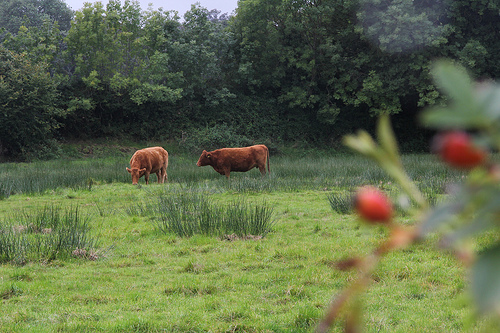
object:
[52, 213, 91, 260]
grass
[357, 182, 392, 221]
flower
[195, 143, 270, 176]
cow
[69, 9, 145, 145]
trees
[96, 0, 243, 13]
sky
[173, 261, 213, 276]
dirt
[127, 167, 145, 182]
head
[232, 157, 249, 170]
stomach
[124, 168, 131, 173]
ear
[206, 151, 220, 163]
neck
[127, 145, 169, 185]
cow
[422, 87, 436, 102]
leaf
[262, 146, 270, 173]
tail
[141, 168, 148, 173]
ear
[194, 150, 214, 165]
head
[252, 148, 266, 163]
hip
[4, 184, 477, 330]
field